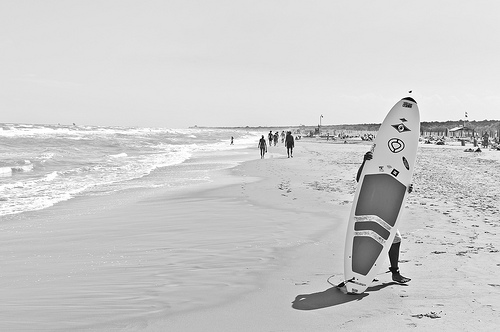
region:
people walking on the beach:
[226, 122, 306, 166]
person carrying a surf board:
[343, 92, 423, 304]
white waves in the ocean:
[0, 110, 222, 212]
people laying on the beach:
[457, 142, 486, 157]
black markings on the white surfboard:
[384, 112, 413, 170]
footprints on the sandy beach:
[422, 161, 494, 240]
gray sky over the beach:
[59, 5, 484, 85]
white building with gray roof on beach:
[420, 119, 481, 144]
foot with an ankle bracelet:
[382, 259, 413, 287]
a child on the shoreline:
[167, 123, 247, 169]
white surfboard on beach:
[333, 101, 422, 290]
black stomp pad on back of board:
[343, 170, 405, 280]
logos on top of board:
[386, 112, 413, 173]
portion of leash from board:
[316, 270, 346, 303]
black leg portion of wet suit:
[388, 240, 406, 280]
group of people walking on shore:
[230, 110, 300, 156]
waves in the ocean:
[12, 142, 204, 214]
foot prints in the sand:
[429, 165, 486, 272]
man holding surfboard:
[313, 94, 420, 294]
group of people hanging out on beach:
[254, 116, 362, 167]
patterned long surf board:
[351, 98, 411, 288]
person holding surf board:
[348, 93, 425, 303]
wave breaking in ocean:
[3, 125, 214, 138]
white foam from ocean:
[3, 193, 75, 215]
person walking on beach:
[283, 133, 295, 157]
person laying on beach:
[465, 147, 482, 154]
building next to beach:
[427, 123, 489, 138]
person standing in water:
[230, 133, 235, 145]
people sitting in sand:
[436, 136, 444, 146]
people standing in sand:
[324, 132, 331, 140]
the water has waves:
[3, 118, 220, 225]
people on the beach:
[225, 109, 499, 163]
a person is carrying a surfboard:
[326, 93, 439, 311]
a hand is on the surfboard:
[356, 147, 390, 177]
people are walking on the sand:
[248, 118, 300, 172]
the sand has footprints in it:
[271, 153, 341, 213]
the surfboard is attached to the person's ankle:
[328, 214, 420, 308]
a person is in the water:
[218, 123, 243, 157]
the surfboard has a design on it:
[341, 94, 428, 298]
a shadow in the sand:
[281, 271, 378, 318]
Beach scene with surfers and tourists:
[1, 3, 496, 327]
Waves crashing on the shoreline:
[3, 128, 220, 203]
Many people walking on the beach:
[253, 127, 303, 155]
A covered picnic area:
[446, 123, 477, 138]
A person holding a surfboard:
[330, 90, 421, 292]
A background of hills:
[420, 107, 495, 142]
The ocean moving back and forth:
[0, 116, 206, 211]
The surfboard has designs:
[355, 95, 410, 291]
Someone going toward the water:
[225, 130, 236, 141]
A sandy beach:
[421, 155, 492, 277]